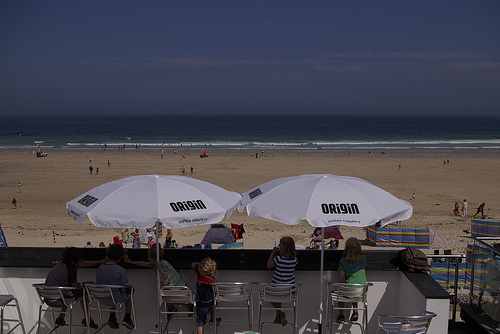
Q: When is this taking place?
A: Daytime.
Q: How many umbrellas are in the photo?
A: Two.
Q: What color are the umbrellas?
A: White and black.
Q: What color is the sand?
A: Tan.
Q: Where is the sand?
A: Beach.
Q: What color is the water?
A: Blue.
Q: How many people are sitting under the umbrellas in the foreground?
A: Six.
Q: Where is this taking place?
A: At the beach.